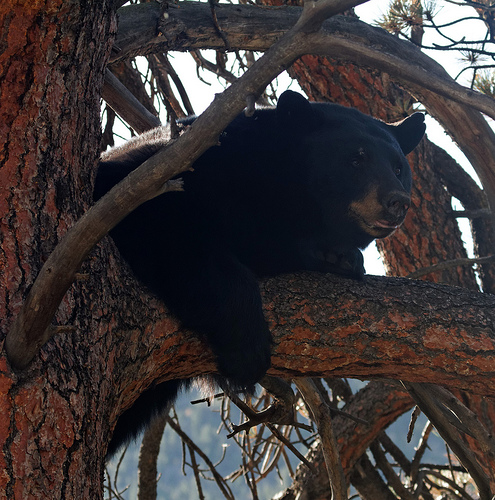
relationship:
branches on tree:
[17, 12, 494, 396] [7, 18, 168, 482]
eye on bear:
[347, 148, 368, 168] [106, 121, 445, 300]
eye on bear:
[386, 153, 406, 176] [106, 121, 445, 300]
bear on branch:
[92, 89, 426, 389] [101, 229, 492, 427]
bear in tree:
[92, 89, 426, 389] [8, 25, 161, 433]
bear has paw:
[101, 91, 425, 390] [190, 284, 283, 391]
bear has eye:
[92, 89, 426, 389] [348, 158, 361, 166]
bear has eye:
[92, 89, 426, 389] [394, 166, 405, 175]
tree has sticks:
[10, 43, 99, 486] [24, 23, 103, 478]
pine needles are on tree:
[382, 1, 409, 34] [0, 0, 490, 497]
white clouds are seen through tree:
[173, 403, 221, 456] [0, 0, 490, 497]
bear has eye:
[101, 91, 425, 390] [350, 149, 364, 167]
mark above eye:
[359, 142, 378, 166] [346, 140, 374, 165]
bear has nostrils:
[92, 89, 426, 389] [388, 192, 412, 211]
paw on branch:
[176, 277, 275, 394] [141, 280, 483, 395]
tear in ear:
[418, 112, 432, 135] [386, 96, 434, 152]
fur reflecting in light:
[188, 373, 223, 402] [185, 376, 223, 417]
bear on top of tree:
[92, 89, 426, 389] [12, 43, 492, 421]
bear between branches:
[92, 89, 426, 389] [28, 2, 483, 497]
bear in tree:
[92, 89, 426, 389] [0, 0, 490, 497]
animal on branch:
[209, 78, 434, 290] [131, 268, 490, 409]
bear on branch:
[92, 89, 426, 389] [352, 272, 491, 401]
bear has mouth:
[92, 89, 426, 389] [354, 181, 419, 241]